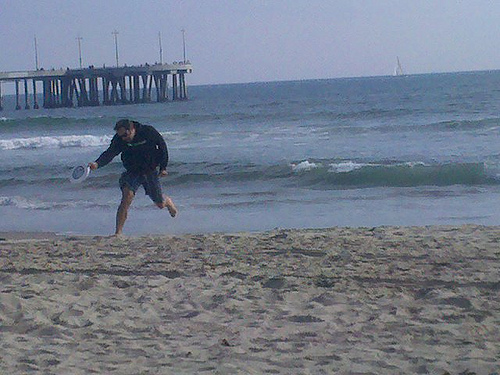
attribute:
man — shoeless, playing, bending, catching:
[88, 117, 178, 239]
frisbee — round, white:
[70, 162, 91, 183]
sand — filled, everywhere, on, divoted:
[7, 226, 499, 365]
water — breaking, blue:
[3, 73, 499, 223]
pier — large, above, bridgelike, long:
[0, 28, 192, 111]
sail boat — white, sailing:
[392, 55, 404, 75]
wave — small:
[2, 130, 181, 152]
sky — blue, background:
[2, 3, 496, 95]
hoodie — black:
[96, 121, 170, 173]